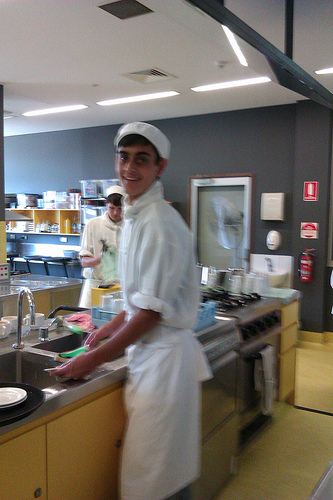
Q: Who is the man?
A: A chef.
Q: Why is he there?
A: He works there.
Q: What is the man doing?
A: Cleaning a dish.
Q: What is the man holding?
A: A plate.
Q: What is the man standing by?
A: A sink.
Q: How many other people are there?
A: One.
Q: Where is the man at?
A: A restaurant.